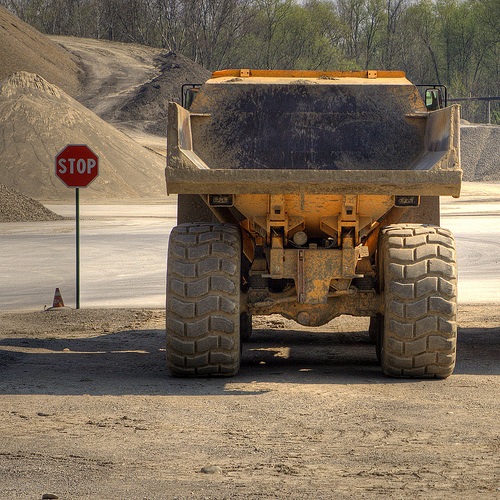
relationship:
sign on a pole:
[30, 124, 122, 181] [74, 207, 79, 237]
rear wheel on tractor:
[164, 222, 241, 379] [163, 65, 462, 385]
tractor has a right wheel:
[163, 65, 462, 385] [380, 264, 381, 327]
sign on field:
[55, 143, 100, 189] [0, 32, 498, 222]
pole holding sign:
[75, 188, 80, 309] [55, 143, 100, 189]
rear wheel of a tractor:
[157, 215, 244, 381] [163, 67, 462, 380]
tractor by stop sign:
[163, 67, 462, 380] [51, 143, 106, 185]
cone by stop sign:
[51, 287, 65, 307] [53, 141, 99, 308]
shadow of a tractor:
[0, 326, 500, 397] [163, 67, 462, 380]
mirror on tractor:
[431, 79, 443, 145] [163, 67, 462, 380]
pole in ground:
[73, 188, 79, 313] [2, 202, 498, 498]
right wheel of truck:
[375, 223, 458, 379] [162, 66, 464, 376]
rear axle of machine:
[242, 285, 383, 322] [158, 65, 462, 379]